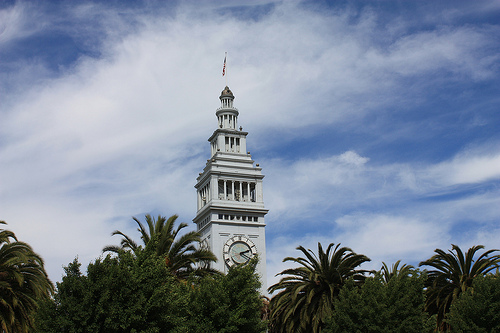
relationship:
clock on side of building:
[221, 233, 260, 280] [190, 80, 274, 314]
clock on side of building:
[197, 237, 212, 277] [192, 94, 274, 307]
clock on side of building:
[197, 237, 212, 277] [190, 80, 274, 314]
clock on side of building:
[221, 233, 260, 280] [190, 79, 270, 302]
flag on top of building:
[215, 53, 230, 73] [190, 79, 280, 329]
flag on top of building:
[215, 53, 230, 73] [190, 80, 274, 314]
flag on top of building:
[215, 53, 230, 73] [199, 77, 263, 311]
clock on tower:
[221, 233, 260, 280] [189, 80, 276, 311]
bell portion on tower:
[189, 175, 264, 208] [193, 83, 267, 328]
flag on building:
[215, 53, 230, 73] [190, 79, 280, 329]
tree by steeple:
[3, 218, 63, 331] [192, 84, 273, 314]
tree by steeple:
[183, 252, 265, 332] [192, 84, 273, 314]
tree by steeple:
[101, 212, 221, 298] [192, 84, 273, 314]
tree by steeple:
[260, 234, 380, 330] [185, 84, 278, 318]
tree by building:
[411, 239, 498, 325] [190, 79, 280, 329]